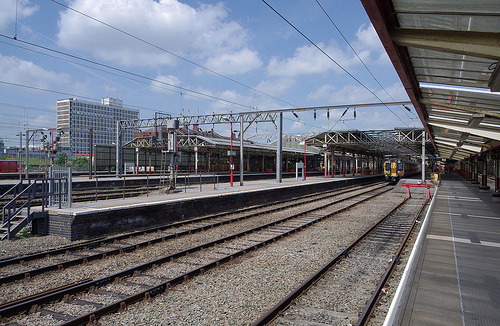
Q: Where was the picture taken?
A: It was taken at the train station.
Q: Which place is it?
A: It is a train station.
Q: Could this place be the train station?
A: Yes, it is the train station.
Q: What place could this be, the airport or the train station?
A: It is the train station.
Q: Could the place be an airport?
A: No, it is a train station.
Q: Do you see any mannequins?
A: No, there are no mannequins.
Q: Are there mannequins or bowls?
A: No, there are no mannequins or bowls.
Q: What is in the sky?
A: The clouds are in the sky.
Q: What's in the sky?
A: The clouds are in the sky.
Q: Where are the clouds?
A: The clouds are in the sky.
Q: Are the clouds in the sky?
A: Yes, the clouds are in the sky.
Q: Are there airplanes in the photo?
A: No, there are no airplanes.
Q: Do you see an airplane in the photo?
A: No, there are no airplanes.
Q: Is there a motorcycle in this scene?
A: No, there are no motorcycles.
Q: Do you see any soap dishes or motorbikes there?
A: No, there are no motorbikes or soap dishes.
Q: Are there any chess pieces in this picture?
A: No, there are no chess pieces.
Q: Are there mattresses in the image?
A: No, there are no mattresses.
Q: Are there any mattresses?
A: No, there are no mattresses.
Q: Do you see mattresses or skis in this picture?
A: No, there are no mattresses or skis.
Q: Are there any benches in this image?
A: Yes, there is a bench.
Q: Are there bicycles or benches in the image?
A: Yes, there is a bench.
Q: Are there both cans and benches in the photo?
A: No, there is a bench but no cans.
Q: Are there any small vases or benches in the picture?
A: Yes, there is a small bench.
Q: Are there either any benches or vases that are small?
A: Yes, the bench is small.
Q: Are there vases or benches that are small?
A: Yes, the bench is small.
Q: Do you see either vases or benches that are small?
A: Yes, the bench is small.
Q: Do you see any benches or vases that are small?
A: Yes, the bench is small.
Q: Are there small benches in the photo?
A: Yes, there is a small bench.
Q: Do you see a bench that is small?
A: Yes, there is a bench that is small.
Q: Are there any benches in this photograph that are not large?
A: Yes, there is a small bench.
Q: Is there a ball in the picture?
A: No, there are no balls.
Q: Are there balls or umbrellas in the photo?
A: No, there are no balls or umbrellas.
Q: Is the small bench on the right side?
A: Yes, the bench is on the right of the image.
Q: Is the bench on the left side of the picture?
A: No, the bench is on the right of the image.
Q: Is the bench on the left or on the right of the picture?
A: The bench is on the right of the image.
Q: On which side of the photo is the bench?
A: The bench is on the right of the image.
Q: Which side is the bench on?
A: The bench is on the right of the image.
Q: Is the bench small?
A: Yes, the bench is small.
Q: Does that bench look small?
A: Yes, the bench is small.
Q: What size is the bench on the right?
A: The bench is small.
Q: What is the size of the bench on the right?
A: The bench is small.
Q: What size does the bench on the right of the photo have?
A: The bench has small size.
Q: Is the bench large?
A: No, the bench is small.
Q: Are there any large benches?
A: No, there is a bench but it is small.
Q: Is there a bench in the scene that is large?
A: No, there is a bench but it is small.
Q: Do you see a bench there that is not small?
A: No, there is a bench but it is small.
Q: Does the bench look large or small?
A: The bench is small.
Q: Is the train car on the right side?
A: Yes, the train car is on the right of the image.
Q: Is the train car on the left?
A: No, the train car is on the right of the image.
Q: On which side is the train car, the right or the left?
A: The train car is on the right of the image.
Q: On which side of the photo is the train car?
A: The train car is on the right of the image.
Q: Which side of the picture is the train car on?
A: The train car is on the right of the image.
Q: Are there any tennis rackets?
A: No, there are no tennis rackets.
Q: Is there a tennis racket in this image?
A: No, there are no rackets.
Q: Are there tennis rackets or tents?
A: No, there are no tennis rackets or tents.